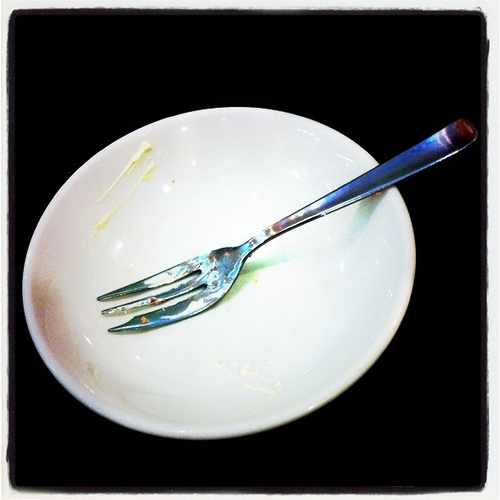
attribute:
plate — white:
[218, 290, 266, 326]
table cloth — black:
[8, 8, 487, 491]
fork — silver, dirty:
[94, 116, 479, 331]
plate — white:
[39, 82, 426, 446]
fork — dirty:
[42, 73, 474, 419]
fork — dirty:
[80, 111, 480, 356]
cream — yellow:
[94, 139, 178, 234]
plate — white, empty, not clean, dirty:
[22, 106, 415, 441]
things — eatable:
[91, 140, 158, 237]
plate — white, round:
[9, 97, 439, 434]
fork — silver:
[103, 109, 487, 339]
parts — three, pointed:
[94, 289, 144, 334]